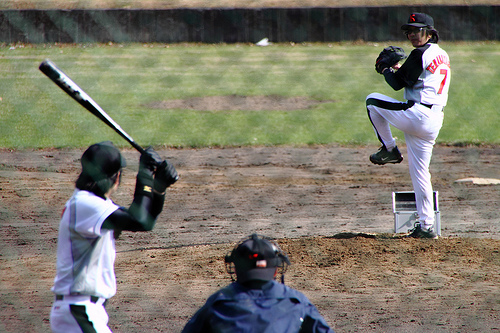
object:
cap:
[222, 232, 291, 290]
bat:
[36, 60, 149, 156]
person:
[183, 232, 335, 333]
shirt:
[50, 189, 119, 297]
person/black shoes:
[367, 143, 405, 166]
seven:
[436, 68, 448, 96]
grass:
[0, 40, 499, 149]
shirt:
[379, 41, 453, 106]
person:
[364, 11, 450, 240]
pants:
[365, 91, 442, 232]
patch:
[135, 94, 341, 113]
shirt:
[176, 281, 333, 332]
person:
[44, 140, 177, 332]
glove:
[134, 146, 164, 176]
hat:
[400, 11, 436, 28]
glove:
[373, 44, 407, 74]